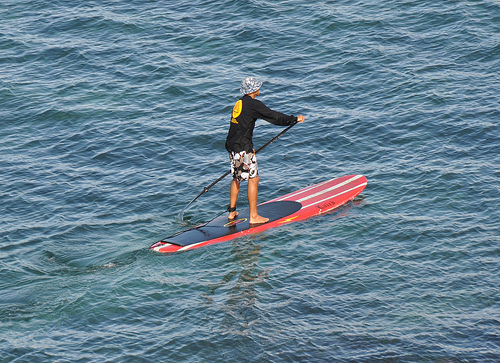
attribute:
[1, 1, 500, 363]
water — blue, white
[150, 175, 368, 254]
board — red, white, in ocean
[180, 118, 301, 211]
paddle — for rowing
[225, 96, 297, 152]
shirt — black, long sleeved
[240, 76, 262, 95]
hat — gray, white, on head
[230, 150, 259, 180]
shorts — brown blue, white, floral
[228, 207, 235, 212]
strap — black